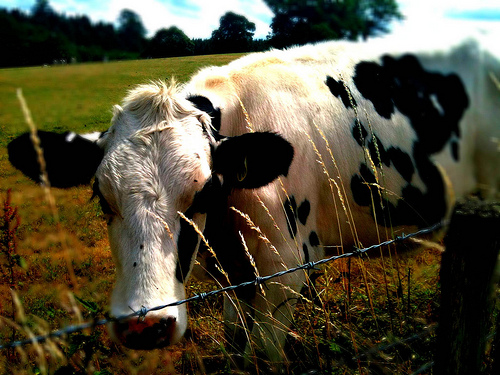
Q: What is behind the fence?
A: Black and white cow.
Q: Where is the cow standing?
A: In a field.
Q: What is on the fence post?
A: Barbed wire.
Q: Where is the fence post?
A: In front of the cow.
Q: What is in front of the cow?
A: Barbed wire.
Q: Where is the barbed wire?
A: Behind the fence post.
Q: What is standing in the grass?
A: A black and white cow.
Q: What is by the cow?
A: A barbed wire fence.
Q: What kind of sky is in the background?
A: Blue and cloudy.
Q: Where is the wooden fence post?
A: By the cow.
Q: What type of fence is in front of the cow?
A: Barbed wire.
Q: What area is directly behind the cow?
A: The field.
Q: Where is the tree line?
A: Behind the cow.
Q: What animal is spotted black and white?
A: A cow.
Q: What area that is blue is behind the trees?
A: The sky.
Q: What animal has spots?
A: The cow.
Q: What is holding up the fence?
A: A piece of wood.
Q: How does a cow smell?
A: With its nose.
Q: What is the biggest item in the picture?
A: A cow.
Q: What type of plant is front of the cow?
A: Wheat.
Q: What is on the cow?
A: Black spots.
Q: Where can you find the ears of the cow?
A: Head.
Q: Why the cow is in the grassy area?
A: Cow can eat.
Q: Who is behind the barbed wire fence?
A: Cow.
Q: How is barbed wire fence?
A: Spinky and new.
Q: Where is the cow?
A: Behind the wire.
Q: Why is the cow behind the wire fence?
A: Cow won't wonder.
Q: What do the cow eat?
A: Grass.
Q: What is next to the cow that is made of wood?
A: Post.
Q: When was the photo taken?
A: Daytime.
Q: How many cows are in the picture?
A: One.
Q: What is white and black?
A: A cow.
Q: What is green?
A: Grass.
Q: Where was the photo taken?
A: In a grassy field.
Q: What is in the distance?
A: Trees.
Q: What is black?
A: Cow's ears.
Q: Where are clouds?
A: In the sky.